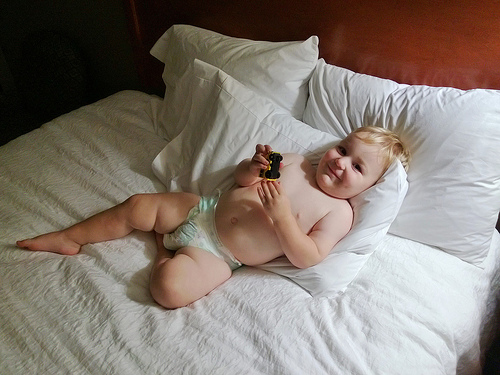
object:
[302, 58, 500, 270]
pillow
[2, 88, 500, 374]
bed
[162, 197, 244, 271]
diaper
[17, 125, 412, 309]
baby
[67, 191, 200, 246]
leg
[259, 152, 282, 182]
toy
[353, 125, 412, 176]
hair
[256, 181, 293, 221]
hand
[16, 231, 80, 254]
foot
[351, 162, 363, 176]
eyes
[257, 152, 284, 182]
truck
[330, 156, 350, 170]
nose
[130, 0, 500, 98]
headboard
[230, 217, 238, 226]
belly button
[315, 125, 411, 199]
head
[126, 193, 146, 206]
knee